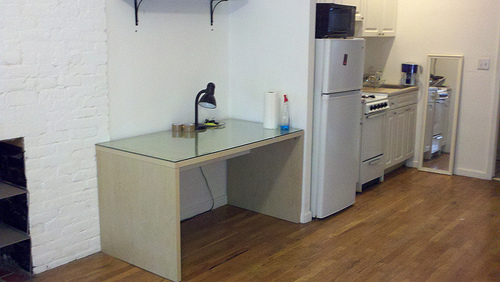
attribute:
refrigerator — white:
[306, 35, 373, 238]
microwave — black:
[314, 0, 375, 50]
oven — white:
[358, 90, 395, 190]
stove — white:
[358, 84, 393, 181]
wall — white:
[26, 5, 118, 150]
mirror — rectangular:
[414, 53, 465, 174]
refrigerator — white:
[290, 50, 403, 278]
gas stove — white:
[357, 87, 389, 197]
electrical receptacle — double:
[474, 56, 491, 73]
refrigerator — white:
[293, 34, 358, 222]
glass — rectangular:
[413, 50, 468, 185]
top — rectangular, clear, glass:
[98, 118, 302, 165]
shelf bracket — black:
[129, 0, 144, 33]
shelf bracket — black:
[207, 0, 226, 28]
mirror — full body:
[416, 55, 466, 178]